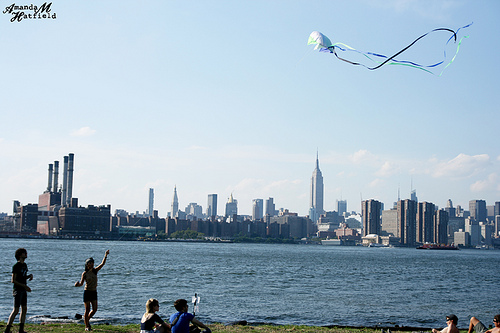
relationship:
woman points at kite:
[78, 250, 111, 332] [286, 22, 499, 96]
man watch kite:
[166, 297, 216, 332] [286, 22, 499, 96]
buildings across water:
[17, 119, 499, 246] [34, 248, 486, 303]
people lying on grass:
[134, 294, 498, 330] [214, 317, 395, 326]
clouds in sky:
[322, 126, 491, 198] [6, 35, 292, 162]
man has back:
[166, 290, 216, 332] [168, 319, 188, 330]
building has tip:
[286, 147, 327, 231] [314, 139, 328, 176]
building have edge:
[306, 147, 327, 218] [320, 176, 326, 201]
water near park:
[34, 248, 486, 303] [19, 244, 472, 331]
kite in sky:
[286, 22, 499, 96] [6, 35, 292, 162]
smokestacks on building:
[30, 144, 76, 202] [33, 178, 118, 235]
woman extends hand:
[78, 250, 111, 332] [100, 253, 111, 268]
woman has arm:
[78, 250, 111, 332] [94, 259, 111, 274]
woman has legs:
[78, 250, 111, 332] [80, 299, 97, 329]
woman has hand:
[78, 250, 111, 332] [100, 253, 111, 268]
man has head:
[166, 290, 216, 332] [171, 296, 193, 319]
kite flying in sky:
[286, 22, 499, 96] [6, 35, 292, 162]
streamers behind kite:
[339, 23, 470, 78] [286, 22, 499, 96]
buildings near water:
[17, 119, 499, 246] [34, 248, 486, 303]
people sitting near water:
[134, 294, 498, 330] [34, 248, 486, 303]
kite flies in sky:
[286, 22, 499, 96] [6, 35, 292, 162]